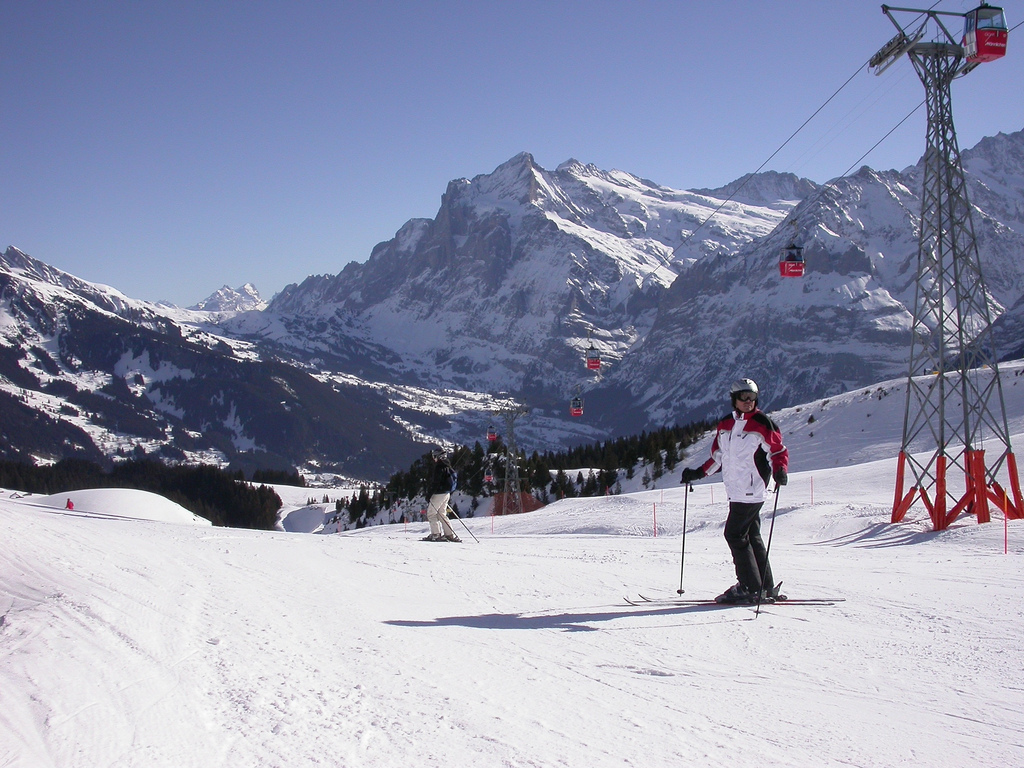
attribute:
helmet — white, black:
[725, 378, 760, 402]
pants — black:
[720, 497, 783, 612]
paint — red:
[892, 448, 1022, 518]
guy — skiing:
[423, 444, 460, 533]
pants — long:
[720, 500, 781, 587]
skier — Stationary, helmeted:
[680, 368, 787, 606]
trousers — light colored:
[423, 491, 452, 531]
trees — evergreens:
[339, 410, 711, 519]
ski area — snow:
[0, 169, 1020, 753]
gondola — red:
[947, 5, 1012, 70]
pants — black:
[720, 502, 779, 598]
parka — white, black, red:
[705, 418, 786, 503]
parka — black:
[418, 457, 464, 492]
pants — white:
[426, 494, 459, 534]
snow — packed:
[5, 383, 1019, 762]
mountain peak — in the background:
[204, 280, 256, 315]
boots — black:
[724, 576, 777, 605]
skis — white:
[612, 588, 850, 625]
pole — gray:
[750, 476, 798, 597]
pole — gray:
[666, 461, 710, 615]